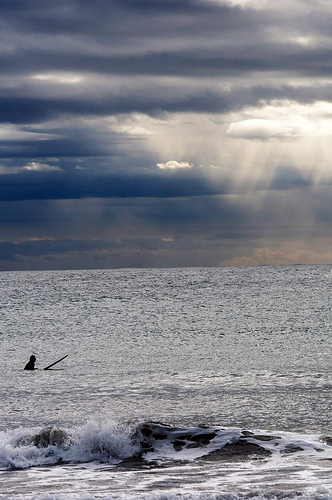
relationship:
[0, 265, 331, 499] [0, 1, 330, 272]
water under clouds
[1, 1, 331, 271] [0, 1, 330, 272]
sunlight shining through clouds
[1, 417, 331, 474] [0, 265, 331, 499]
wave in water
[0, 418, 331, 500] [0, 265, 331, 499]
white foam in water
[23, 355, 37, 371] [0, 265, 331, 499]
surfer in water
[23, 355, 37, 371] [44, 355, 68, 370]
surfer holding surfboard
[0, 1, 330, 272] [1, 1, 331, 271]
clouds are in sky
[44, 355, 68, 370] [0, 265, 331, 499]
surfboard stickout of water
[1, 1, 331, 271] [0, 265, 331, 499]
sky meets water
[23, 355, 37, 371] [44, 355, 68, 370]
surfer near surfboard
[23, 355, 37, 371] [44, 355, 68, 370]
surfer next to surfboard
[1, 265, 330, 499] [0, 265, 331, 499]
ripples are in water